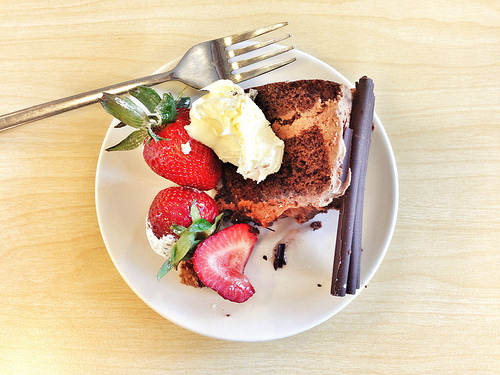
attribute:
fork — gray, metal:
[6, 8, 306, 181]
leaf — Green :
[98, 85, 189, 151]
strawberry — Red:
[97, 85, 221, 189]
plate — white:
[88, 37, 432, 369]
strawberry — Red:
[149, 185, 217, 260]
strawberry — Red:
[142, 103, 218, 189]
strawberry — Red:
[192, 223, 258, 306]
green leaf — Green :
[170, 216, 214, 256]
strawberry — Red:
[200, 224, 261, 305]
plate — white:
[85, 33, 401, 347]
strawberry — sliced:
[189, 220, 259, 305]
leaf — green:
[91, 80, 179, 160]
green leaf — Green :
[181, 205, 203, 239]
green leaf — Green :
[90, 85, 195, 139]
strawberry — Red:
[129, 127, 214, 185]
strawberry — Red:
[139, 186, 241, 242]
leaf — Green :
[160, 92, 177, 122]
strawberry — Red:
[142, 108, 220, 191]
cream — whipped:
[177, 76, 289, 191]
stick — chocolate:
[330, 75, 379, 302]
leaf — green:
[129, 83, 176, 118]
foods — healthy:
[101, 82, 372, 302]